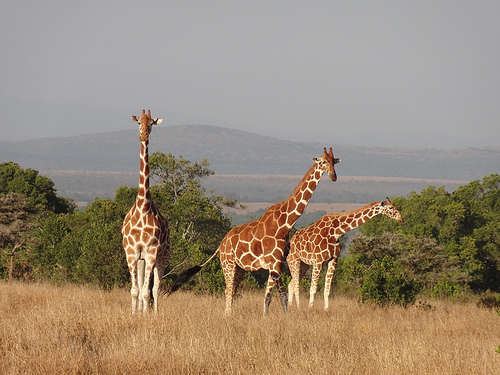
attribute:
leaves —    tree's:
[338, 172, 498, 307]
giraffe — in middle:
[162, 147, 340, 316]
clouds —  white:
[62, 8, 142, 48]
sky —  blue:
[2, 0, 499, 239]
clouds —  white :
[44, 92, 99, 128]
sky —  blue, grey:
[2, 1, 499, 136]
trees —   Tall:
[338, 150, 497, 317]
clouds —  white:
[228, 54, 316, 95]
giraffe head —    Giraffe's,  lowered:
[376, 199, 415, 228]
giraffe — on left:
[115, 105, 177, 328]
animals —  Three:
[115, 103, 430, 315]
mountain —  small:
[3, 121, 499, 183]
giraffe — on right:
[281, 195, 403, 317]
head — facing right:
[381, 195, 403, 227]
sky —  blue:
[15, 17, 482, 99]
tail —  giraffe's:
[164, 244, 221, 300]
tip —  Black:
[162, 267, 201, 292]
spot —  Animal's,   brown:
[314, 167, 319, 179]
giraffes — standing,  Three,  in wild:
[118, 105, 405, 318]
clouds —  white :
[12, 80, 82, 100]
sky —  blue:
[5, 7, 497, 107]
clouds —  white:
[170, 96, 243, 122]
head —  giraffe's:
[130, 105, 164, 144]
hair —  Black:
[167, 264, 201, 293]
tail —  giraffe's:
[163, 246, 215, 297]